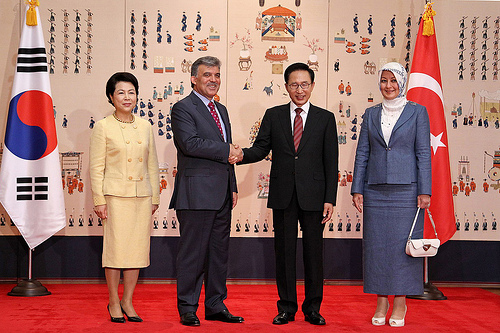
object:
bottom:
[5, 279, 53, 295]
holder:
[7, 277, 51, 296]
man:
[168, 56, 243, 326]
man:
[228, 63, 339, 326]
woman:
[351, 62, 432, 327]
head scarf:
[378, 62, 408, 98]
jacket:
[351, 101, 430, 195]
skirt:
[363, 182, 424, 295]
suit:
[236, 101, 338, 314]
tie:
[294, 108, 304, 152]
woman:
[90, 72, 161, 323]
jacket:
[89, 112, 160, 206]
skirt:
[101, 195, 152, 268]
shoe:
[304, 311, 326, 326]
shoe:
[272, 311, 295, 325]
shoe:
[205, 309, 244, 323]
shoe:
[180, 312, 200, 327]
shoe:
[389, 304, 408, 327]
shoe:
[371, 300, 389, 325]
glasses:
[289, 83, 309, 90]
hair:
[191, 56, 222, 89]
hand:
[228, 143, 244, 162]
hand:
[228, 144, 240, 164]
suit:
[169, 90, 238, 315]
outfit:
[90, 113, 160, 269]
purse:
[405, 207, 441, 258]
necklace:
[112, 111, 135, 124]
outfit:
[351, 101, 432, 296]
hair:
[284, 63, 315, 84]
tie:
[207, 102, 224, 142]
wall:
[0, 0, 500, 284]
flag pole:
[28, 248, 33, 279]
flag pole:
[423, 256, 429, 284]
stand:
[405, 284, 447, 301]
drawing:
[255, 4, 303, 41]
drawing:
[230, 29, 254, 70]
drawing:
[302, 35, 324, 70]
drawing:
[264, 45, 289, 63]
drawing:
[243, 71, 253, 90]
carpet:
[0, 283, 499, 332]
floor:
[0, 280, 499, 332]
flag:
[406, 0, 457, 245]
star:
[429, 132, 446, 155]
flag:
[0, 6, 66, 250]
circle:
[4, 90, 57, 161]